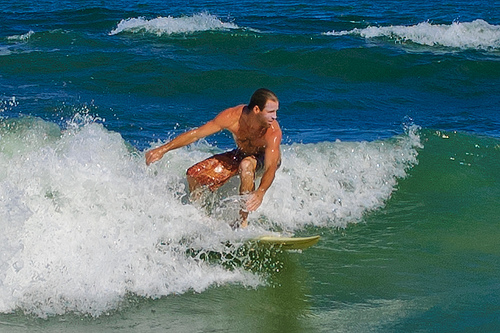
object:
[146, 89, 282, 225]
man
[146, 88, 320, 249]
surfing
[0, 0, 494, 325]
ocean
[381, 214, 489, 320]
green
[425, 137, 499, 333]
water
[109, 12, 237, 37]
small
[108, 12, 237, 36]
crashing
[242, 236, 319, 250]
surfboard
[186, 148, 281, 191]
shorts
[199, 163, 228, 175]
orange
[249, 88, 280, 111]
hair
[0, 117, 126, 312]
waves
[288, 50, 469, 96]
blue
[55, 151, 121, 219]
white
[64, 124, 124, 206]
splash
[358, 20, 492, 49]
wave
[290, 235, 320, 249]
nose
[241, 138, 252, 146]
hair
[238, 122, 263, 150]
chest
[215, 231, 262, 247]
hidden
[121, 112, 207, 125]
water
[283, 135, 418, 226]
churned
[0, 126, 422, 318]
riding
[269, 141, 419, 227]
waves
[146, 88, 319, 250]
standing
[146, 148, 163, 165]
hand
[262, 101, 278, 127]
face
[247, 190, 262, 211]
hand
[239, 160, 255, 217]
leg